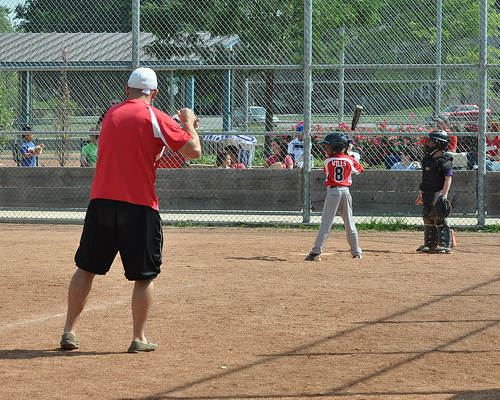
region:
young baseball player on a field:
[301, 103, 367, 261]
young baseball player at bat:
[303, 101, 366, 261]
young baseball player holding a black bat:
[300, 102, 367, 262]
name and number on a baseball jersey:
[327, 158, 349, 183]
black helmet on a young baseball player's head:
[321, 132, 351, 157]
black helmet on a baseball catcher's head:
[425, 129, 451, 150]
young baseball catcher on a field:
[412, 125, 459, 254]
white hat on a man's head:
[124, 66, 158, 90]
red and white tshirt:
[87, 96, 192, 211]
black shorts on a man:
[73, 198, 165, 280]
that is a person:
[55, 55, 203, 370]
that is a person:
[260, 135, 290, 170]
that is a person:
[385, 140, 410, 175]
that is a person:
[10, 125, 35, 170]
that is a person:
[285, 116, 301, 176]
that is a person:
[67, 122, 98, 167]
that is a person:
[305, 105, 360, 275]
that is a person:
[415, 122, 465, 267]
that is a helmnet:
[325, 130, 342, 155]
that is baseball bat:
[348, 100, 361, 145]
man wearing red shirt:
[55, 58, 199, 353]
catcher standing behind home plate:
[423, 126, 455, 253]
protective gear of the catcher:
[415, 126, 454, 249]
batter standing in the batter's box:
[305, 99, 367, 259]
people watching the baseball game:
[5, 95, 496, 172]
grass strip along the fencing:
[8, 210, 497, 231]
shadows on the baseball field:
[165, 273, 497, 398]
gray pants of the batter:
[308, 187, 358, 248]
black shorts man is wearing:
[74, 197, 155, 280]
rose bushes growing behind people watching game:
[266, 121, 499, 162]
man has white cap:
[109, 66, 164, 101]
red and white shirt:
[108, 91, 193, 193]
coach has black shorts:
[66, 182, 164, 303]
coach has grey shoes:
[45, 293, 168, 375]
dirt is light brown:
[194, 309, 341, 382]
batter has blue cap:
[316, 129, 339, 141]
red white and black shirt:
[324, 156, 354, 186]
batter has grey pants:
[291, 183, 351, 255]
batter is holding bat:
[340, 100, 368, 141]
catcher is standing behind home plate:
[405, 128, 472, 270]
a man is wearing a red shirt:
[85, 88, 286, 222]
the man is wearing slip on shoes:
[27, 312, 287, 374]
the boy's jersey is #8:
[305, 146, 408, 183]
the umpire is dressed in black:
[415, 140, 492, 265]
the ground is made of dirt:
[212, 273, 408, 375]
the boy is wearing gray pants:
[326, 178, 444, 322]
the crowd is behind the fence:
[211, 100, 332, 175]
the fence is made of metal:
[221, 50, 342, 180]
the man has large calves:
[60, 273, 305, 325]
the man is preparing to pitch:
[157, 107, 278, 197]